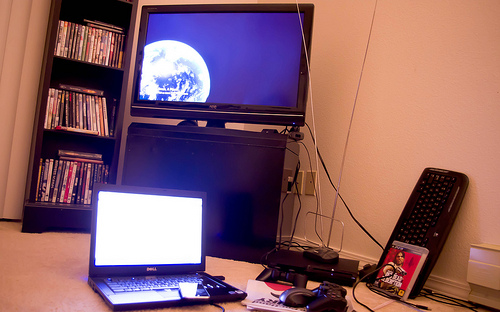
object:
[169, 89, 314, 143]
stand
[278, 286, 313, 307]
mouse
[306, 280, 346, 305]
remote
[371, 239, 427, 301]
video game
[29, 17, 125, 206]
dvd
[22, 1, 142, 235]
bookcase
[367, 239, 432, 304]
case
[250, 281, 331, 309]
mouse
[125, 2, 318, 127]
flat-screen television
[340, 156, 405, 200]
wall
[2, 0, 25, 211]
wall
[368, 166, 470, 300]
black keyboard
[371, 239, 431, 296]
red cd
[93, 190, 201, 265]
screen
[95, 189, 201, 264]
lit screen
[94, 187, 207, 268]
white screen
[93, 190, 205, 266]
bright screen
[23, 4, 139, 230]
movie shelf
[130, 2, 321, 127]
television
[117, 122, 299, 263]
stand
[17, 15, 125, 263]
shelves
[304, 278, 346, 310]
play station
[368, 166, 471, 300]
keyboard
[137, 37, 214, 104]
moon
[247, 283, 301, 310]
remote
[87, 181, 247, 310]
laptop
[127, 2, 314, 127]
tv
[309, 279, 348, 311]
controller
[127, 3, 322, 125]
pizza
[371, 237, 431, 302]
movie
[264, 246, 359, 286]
cd player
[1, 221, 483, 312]
carpet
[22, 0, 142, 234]
shelf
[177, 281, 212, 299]
cell phone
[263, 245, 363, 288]
laptop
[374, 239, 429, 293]
videogame case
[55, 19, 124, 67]
movies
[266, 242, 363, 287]
system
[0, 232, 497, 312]
floor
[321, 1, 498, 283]
walls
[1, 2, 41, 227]
walls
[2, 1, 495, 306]
living room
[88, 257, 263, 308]
keyboard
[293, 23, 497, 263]
wall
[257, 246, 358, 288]
playstation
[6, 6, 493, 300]
wall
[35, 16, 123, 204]
cds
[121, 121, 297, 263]
platform